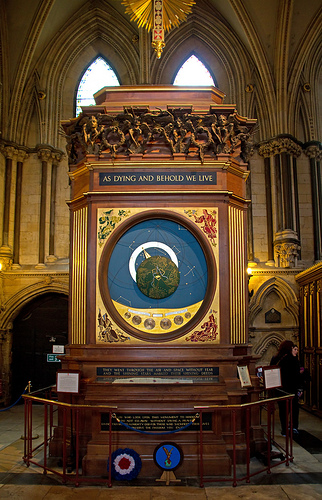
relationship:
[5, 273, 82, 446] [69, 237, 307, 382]
doorway next wall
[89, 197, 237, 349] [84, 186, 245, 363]
device on side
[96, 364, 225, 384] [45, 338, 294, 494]
writing on side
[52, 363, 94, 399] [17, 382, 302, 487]
sign behind barrier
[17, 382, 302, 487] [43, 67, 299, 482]
barrier around tower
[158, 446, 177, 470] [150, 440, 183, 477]
eagle in picture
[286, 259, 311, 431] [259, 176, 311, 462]
case on side